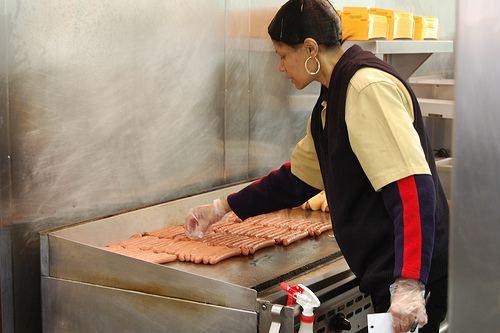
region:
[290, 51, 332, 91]
Large hoop earring on person's ear.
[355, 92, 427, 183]
Tan t-shirt over blue shirt.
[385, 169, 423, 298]
Red stripe down blue shirt sleeve.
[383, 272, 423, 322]
Clear gloves on person's hands.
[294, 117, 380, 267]
Black vest over person's shirt.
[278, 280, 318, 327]
Red and white spray bottle on grill.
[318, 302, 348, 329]
Black knob on oven.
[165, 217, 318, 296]
Flat top silver grill.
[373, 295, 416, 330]
Person is holding paper and pen.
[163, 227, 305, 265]
Many hot dogs on top of grill.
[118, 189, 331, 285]
these are hot dogs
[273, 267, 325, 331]
this is a nozzel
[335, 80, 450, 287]
this is a sleeve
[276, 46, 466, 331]
this is a vest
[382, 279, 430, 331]
this is the left glove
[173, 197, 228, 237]
this is the right glove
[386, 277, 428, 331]
this is the left hand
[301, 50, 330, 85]
this is a earring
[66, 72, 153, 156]
this is a wall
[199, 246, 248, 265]
the hot dog in orange color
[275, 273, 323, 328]
the white color spray bottle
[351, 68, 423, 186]
the yellow color t shirt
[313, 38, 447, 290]
the brown color sweater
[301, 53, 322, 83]
the ear ring of an women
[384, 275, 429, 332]
the cover on the women hand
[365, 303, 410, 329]
the white color phone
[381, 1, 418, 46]
the yellow color packet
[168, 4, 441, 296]
the girl arranging hot dogs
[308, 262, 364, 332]
the stove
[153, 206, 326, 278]
Hot dogs on a griddle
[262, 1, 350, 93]
Woman wearing a hair net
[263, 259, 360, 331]
Water bottle hanging on a stove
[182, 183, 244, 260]
Person wearing plastic gloves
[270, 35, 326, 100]
Woman with a gold hoop earring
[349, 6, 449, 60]
Yellow boxes on a shelf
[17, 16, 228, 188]
Silver colored metal wall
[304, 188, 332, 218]
Hot dog buns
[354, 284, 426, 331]
Person holding a piece of paper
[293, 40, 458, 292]
Person wearing a black vest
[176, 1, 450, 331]
a woman cooking over grill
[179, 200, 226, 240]
clear plastic protective glove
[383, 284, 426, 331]
clear plastic protective glove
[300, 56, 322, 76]
a gold hoop earring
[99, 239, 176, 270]
a row of cooking hot dogs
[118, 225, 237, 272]
a row of cooking hot dogs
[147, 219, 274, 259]
a row of cooking hot dogs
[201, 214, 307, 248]
a row of cooking hot dogs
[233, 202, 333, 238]
a row of cooking hot dogs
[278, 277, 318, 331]
a red and white spray bottle